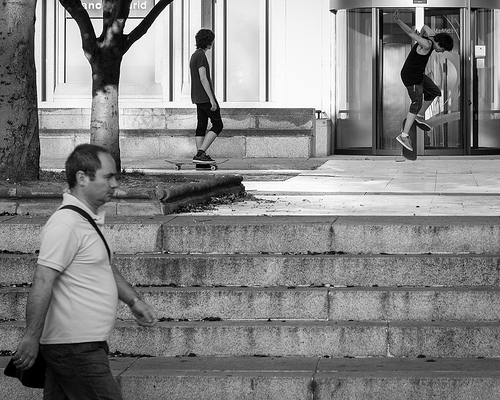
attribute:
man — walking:
[24, 141, 156, 391]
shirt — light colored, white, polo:
[32, 196, 131, 337]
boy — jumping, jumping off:
[382, 9, 459, 166]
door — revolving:
[363, 3, 484, 157]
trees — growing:
[2, 1, 139, 182]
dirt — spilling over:
[265, 195, 299, 215]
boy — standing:
[191, 32, 243, 158]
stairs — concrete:
[272, 209, 433, 370]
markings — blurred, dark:
[150, 252, 226, 294]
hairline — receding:
[89, 142, 120, 168]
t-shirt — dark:
[184, 51, 224, 112]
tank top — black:
[403, 37, 434, 88]